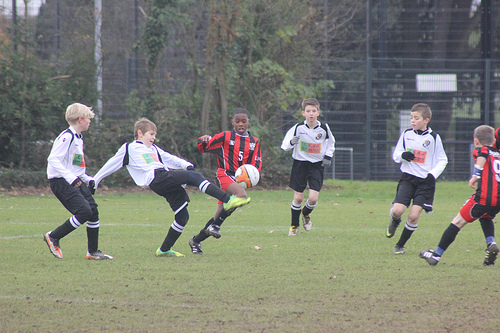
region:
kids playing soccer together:
[31, 53, 494, 290]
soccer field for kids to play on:
[7, 15, 496, 320]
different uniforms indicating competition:
[117, 87, 265, 271]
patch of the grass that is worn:
[76, 228, 486, 330]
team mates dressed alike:
[289, 89, 461, 249]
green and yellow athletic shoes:
[146, 200, 294, 300]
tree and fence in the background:
[123, 85, 410, 299]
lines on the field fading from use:
[4, 204, 366, 331]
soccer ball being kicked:
[211, 154, 283, 253]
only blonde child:
[43, 82, 118, 147]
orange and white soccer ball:
[232, 161, 264, 189]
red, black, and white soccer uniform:
[198, 130, 270, 194]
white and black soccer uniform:
[283, 119, 335, 198]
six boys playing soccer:
[21, 89, 498, 271]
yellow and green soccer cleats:
[221, 194, 254, 214]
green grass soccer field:
[16, 192, 428, 332]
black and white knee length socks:
[286, 198, 318, 235]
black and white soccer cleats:
[415, 246, 445, 266]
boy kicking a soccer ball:
[110, 114, 268, 261]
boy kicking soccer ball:
[192, 103, 274, 253]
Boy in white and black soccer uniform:
[38, 100, 118, 270]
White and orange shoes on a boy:
[36, 216, 145, 267]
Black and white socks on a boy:
[31, 213, 143, 270]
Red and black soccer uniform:
[194, 106, 267, 216]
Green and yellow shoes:
[148, 204, 250, 269]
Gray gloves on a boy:
[276, 126, 346, 171]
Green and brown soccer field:
[239, 233, 409, 313]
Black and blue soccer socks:
[413, 209, 498, 295]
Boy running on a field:
[281, 94, 347, 246]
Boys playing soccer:
[25, 96, 430, 289]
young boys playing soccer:
[34, 52, 499, 299]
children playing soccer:
[41, 49, 470, 299]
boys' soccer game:
[116, 84, 279, 260]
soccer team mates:
[284, 72, 441, 259]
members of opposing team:
[116, 83, 276, 259]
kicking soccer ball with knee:
[186, 92, 281, 253]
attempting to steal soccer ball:
[108, 81, 275, 293]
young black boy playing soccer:
[196, 105, 272, 260]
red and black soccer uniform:
[198, 95, 273, 260]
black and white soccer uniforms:
[48, 90, 195, 271]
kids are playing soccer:
[43, 96, 498, 267]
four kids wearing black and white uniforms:
[44, 96, 447, 263]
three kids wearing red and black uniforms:
[186, 106, 498, 266]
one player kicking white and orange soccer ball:
[234, 162, 260, 187]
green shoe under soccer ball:
[222, 193, 251, 211]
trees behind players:
[0, 0, 390, 167]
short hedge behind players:
[0, 161, 293, 196]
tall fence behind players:
[0, 0, 498, 181]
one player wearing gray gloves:
[291, 135, 332, 167]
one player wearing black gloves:
[401, 151, 434, 184]